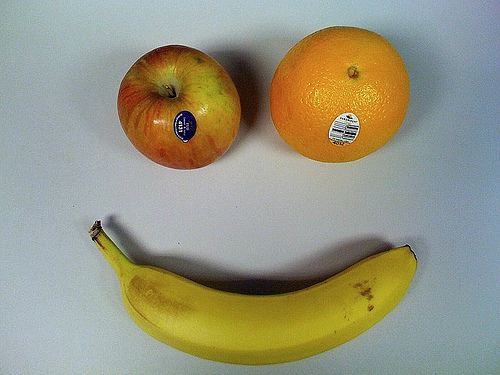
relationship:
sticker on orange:
[328, 109, 360, 150] [274, 25, 408, 167]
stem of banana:
[87, 217, 132, 277] [73, 218, 417, 368]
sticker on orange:
[322, 108, 357, 148] [264, 24, 413, 166]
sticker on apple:
[170, 109, 198, 142] [114, 39, 242, 173]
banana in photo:
[89, 218, 417, 365] [3, 52, 493, 303]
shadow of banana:
[132, 248, 389, 297] [73, 218, 417, 368]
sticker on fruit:
[329, 111, 357, 146] [271, 27, 407, 163]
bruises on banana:
[356, 275, 372, 298] [79, 217, 458, 368]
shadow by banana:
[105, 214, 430, 314] [73, 218, 417, 368]